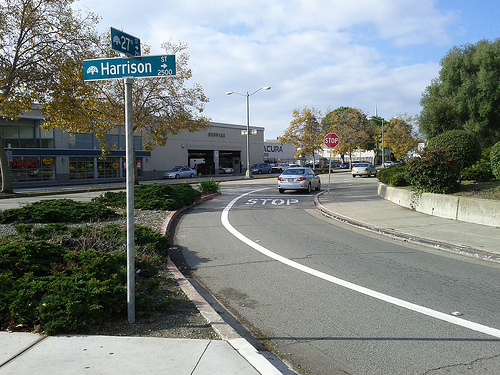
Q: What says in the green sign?
A: Harrison.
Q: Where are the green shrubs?
A: Behind the sign.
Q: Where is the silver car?
A: Near the stop sign.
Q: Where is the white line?
A: In the center of the road.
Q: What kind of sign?
A: Street.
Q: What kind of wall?
A: Cement.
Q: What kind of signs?
A: Street.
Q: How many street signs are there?
A: 2.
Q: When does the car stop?
A: At the stop sign.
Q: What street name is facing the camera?
A: Harrison.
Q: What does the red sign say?
A: Stop.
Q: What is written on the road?
A: Stop.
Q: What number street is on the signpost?
A: 27th.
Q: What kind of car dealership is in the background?
A: Acura.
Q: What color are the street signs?
A: Green.